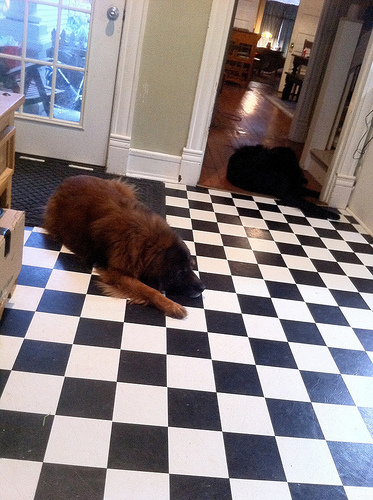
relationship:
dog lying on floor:
[43, 174, 207, 319] [0, 154, 370, 499]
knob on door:
[107, 4, 122, 22] [4, 2, 128, 166]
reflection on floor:
[230, 83, 270, 120] [196, 75, 328, 204]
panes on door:
[1, 1, 92, 131] [4, 2, 128, 166]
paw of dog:
[165, 299, 192, 325] [43, 167, 208, 321]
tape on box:
[2, 225, 16, 255] [0, 206, 33, 319]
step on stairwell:
[310, 145, 337, 184] [307, 56, 372, 186]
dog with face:
[43, 167, 208, 321] [164, 257, 214, 298]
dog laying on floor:
[223, 140, 347, 221] [0, 154, 370, 499]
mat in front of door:
[7, 152, 165, 243] [4, 2, 128, 166]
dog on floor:
[43, 167, 208, 321] [0, 154, 370, 499]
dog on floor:
[223, 140, 347, 221] [0, 154, 370, 499]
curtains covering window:
[256, 1, 299, 52] [259, 0, 298, 57]